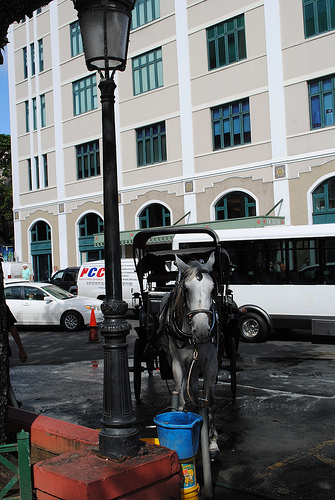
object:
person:
[23, 288, 36, 300]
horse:
[157, 248, 231, 452]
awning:
[93, 215, 285, 247]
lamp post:
[99, 78, 141, 462]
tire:
[64, 309, 81, 331]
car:
[0, 278, 105, 331]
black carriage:
[133, 225, 243, 400]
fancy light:
[74, 0, 136, 71]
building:
[5, 0, 334, 290]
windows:
[242, 112, 250, 145]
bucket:
[180, 459, 200, 495]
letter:
[87, 265, 98, 277]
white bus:
[170, 222, 334, 344]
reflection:
[89, 344, 100, 371]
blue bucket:
[153, 409, 201, 459]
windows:
[287, 238, 319, 285]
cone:
[89, 308, 98, 329]